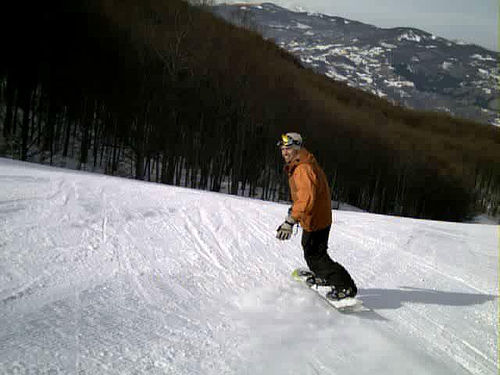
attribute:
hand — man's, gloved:
[263, 205, 330, 249]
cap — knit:
[275, 130, 301, 149]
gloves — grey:
[271, 211, 301, 245]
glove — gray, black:
[275, 206, 294, 240]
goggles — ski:
[275, 133, 302, 147]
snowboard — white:
[298, 245, 382, 327]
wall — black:
[192, 93, 302, 154]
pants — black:
[301, 218, 362, 295]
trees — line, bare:
[12, 11, 494, 216]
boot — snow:
[296, 267, 388, 312]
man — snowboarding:
[274, 127, 358, 299]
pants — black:
[276, 214, 367, 291]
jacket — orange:
[278, 149, 335, 234]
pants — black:
[302, 221, 356, 291]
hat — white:
[275, 126, 311, 165]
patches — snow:
[0, 156, 465, 372]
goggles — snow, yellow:
[274, 128, 307, 150]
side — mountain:
[2, 1, 483, 220]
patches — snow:
[275, 4, 445, 118]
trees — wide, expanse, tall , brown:
[0, 0, 484, 234]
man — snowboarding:
[268, 127, 366, 315]